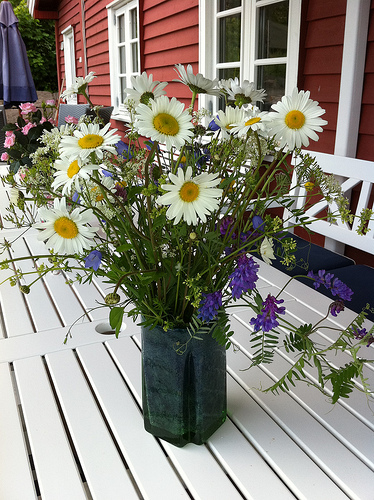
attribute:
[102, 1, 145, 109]
window — white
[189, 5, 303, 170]
window — white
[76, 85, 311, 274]
daisies — some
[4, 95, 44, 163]
flowers — pink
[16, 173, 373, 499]
table — white, wooden, long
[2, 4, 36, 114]
umbrella — faded, blue, patio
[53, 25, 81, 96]
door — white, back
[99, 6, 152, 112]
window — white, framed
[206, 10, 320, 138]
window — framed, white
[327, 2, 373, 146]
downspout — white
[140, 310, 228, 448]
vase — green, tinted, glass, purple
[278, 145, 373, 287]
bench — white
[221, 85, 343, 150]
flowers — white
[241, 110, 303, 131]
centers — yellow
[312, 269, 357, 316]
flowers — dark, purple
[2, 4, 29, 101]
umbrella — purple, patio, closed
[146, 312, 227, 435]
vase — green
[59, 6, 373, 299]
house — painted, red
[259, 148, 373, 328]
bench — white, wooden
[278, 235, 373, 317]
cushions — blue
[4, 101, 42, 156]
roses — pink, light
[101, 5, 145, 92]
windows — framed, wooden, white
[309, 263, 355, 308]
flower — blue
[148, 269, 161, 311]
stem — floral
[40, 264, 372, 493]
table — white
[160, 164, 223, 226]
flower — white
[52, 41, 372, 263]
house — red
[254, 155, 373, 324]
chair — white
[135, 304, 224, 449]
vase — one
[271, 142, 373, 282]
bench — white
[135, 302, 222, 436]
vase — flower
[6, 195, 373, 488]
table — white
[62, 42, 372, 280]
house — red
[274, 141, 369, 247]
bench — white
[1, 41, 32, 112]
umbrella — large, purple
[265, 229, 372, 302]
cushion — blue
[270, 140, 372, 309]
bench — white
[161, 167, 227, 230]
flower — white, small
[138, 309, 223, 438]
vase — green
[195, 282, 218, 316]
flower — small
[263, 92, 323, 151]
flower — white, small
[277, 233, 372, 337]
cushion — blue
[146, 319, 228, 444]
vase — one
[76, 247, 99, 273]
flower — small, blue